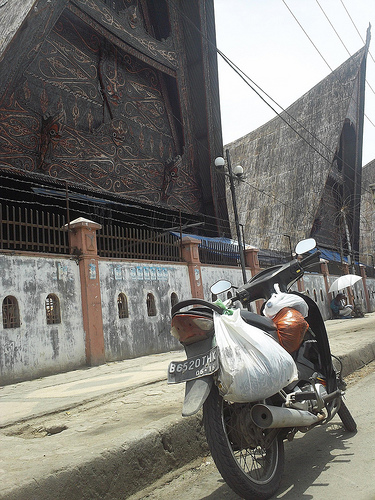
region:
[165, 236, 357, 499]
Motorcycle parked near sidewalk.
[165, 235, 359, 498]
Plastic bags tied to motorcycle.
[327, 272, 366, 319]
People sitting on sidewalk.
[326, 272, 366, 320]
People sitting on sidewalk under umbrella.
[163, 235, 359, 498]
White plastic bags tied to motorcycle.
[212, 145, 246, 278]
Street lamp near sidewalk.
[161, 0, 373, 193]
Electricity overhead wires over sidewalk.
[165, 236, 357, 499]
Black motorcycle parked near sidewalk.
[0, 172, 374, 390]
Wall with barbed wires.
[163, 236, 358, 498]
Orange bag on black motorcycle.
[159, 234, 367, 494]
a small motorcycle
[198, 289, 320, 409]
grocery bags hanging on a motorcycle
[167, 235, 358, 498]
the motorcycle is parked at the side of the road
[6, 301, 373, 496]
a curb beside the motorcycle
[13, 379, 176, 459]
the curb is falling apart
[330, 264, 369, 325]
a person sitting on the ground against a wall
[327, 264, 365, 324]
the person by the wall is holding a white umbrella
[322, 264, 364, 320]
an open white umbrella over a person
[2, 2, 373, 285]
buildings with tall steep roofs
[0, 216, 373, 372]
a concrete wall with metal railings over the windows and on the top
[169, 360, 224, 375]
number plate of a bike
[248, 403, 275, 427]
the exhaust pipe of a bike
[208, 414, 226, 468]
the rubber tyre of a bike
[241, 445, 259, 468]
spokes on the wheel of a bike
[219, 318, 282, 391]
a white paper bag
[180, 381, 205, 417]
a mud guard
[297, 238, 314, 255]
side mirror of a bike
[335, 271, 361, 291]
an umbrella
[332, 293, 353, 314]
a person seated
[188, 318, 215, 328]
rear light of a bike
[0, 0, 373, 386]
the large building next to the sidewalk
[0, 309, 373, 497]
the sidewalk next to the motorcycle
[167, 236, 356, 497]
the motorcycle parked next to the sidewalk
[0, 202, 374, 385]
the wall next to the building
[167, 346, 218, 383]
the license plate on the motorcycle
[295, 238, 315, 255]
the mirror on the motorcycle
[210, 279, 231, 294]
the mirror on the motorcycle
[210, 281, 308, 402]
the bags hanging off of the motorcycle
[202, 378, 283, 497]
the wheel on the back of the motorcycle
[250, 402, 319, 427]
the muffler on the motorcycle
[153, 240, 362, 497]
motorcycle parked on the side of the road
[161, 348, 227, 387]
black and white license plate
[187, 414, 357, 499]
shadow on the ground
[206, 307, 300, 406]
plastic bag hanging off the bike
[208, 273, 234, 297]
mirror on the side of the bike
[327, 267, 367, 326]
person sitting under an umbrella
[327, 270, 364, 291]
bright white umbrella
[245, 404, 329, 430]
exhaust pipe on the bike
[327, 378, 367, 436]
front wheel is turned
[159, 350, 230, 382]
license plate on the back of the bike